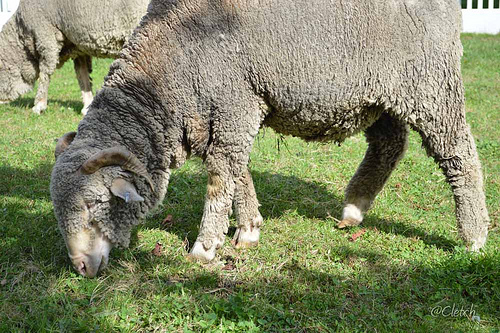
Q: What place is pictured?
A: It is a field.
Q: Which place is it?
A: It is a field.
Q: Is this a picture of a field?
A: Yes, it is showing a field.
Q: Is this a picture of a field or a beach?
A: It is showing a field.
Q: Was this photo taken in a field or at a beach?
A: It was taken at a field.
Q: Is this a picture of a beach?
A: No, the picture is showing a field.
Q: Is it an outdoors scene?
A: Yes, it is outdoors.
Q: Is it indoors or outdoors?
A: It is outdoors.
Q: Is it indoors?
A: No, it is outdoors.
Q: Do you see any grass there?
A: Yes, there is grass.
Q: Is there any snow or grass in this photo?
A: Yes, there is grass.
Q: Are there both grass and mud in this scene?
A: No, there is grass but no mud.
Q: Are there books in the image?
A: No, there are no books.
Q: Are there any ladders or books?
A: No, there are no books or ladders.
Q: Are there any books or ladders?
A: No, there are no books or ladders.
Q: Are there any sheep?
A: Yes, there is a sheep.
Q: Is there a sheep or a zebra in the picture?
A: Yes, there is a sheep.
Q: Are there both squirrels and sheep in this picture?
A: No, there is a sheep but no squirrels.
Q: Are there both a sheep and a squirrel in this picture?
A: No, there is a sheep but no squirrels.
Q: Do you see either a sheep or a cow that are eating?
A: Yes, the sheep is eating.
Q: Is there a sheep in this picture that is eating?
A: Yes, there is a sheep that is eating.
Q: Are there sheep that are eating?
A: Yes, there is a sheep that is eating.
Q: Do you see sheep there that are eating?
A: Yes, there is a sheep that is eating.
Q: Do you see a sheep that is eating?
A: Yes, there is a sheep that is eating.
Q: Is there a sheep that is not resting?
A: Yes, there is a sheep that is eating.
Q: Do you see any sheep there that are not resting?
A: Yes, there is a sheep that is eating .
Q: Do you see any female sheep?
A: Yes, there is a female sheep.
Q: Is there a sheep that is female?
A: Yes, there is a sheep that is female.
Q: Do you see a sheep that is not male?
A: Yes, there is a female sheep.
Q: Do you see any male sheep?
A: Yes, there is a male sheep.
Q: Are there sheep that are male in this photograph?
A: Yes, there is a male sheep.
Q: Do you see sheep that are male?
A: Yes, there is a sheep that is male.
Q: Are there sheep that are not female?
A: Yes, there is a male sheep.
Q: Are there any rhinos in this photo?
A: No, there are no rhinos.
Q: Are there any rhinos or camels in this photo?
A: No, there are no rhinos or camels.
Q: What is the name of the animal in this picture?
A: The animal is a sheep.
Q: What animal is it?
A: The animal is a sheep.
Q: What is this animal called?
A: This is a sheep.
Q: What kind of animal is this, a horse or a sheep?
A: This is a sheep.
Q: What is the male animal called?
A: The animal is a sheep.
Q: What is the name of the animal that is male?
A: The animal is a sheep.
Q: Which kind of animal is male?
A: The animal is a sheep.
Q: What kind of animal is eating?
A: The animal is a sheep.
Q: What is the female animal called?
A: The animal is a sheep.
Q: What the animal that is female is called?
A: The animal is a sheep.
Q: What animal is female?
A: The animal is a sheep.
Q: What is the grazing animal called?
A: The animal is a sheep.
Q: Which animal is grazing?
A: The animal is a sheep.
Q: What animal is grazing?
A: The animal is a sheep.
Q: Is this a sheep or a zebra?
A: This is a sheep.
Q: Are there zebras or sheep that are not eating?
A: No, there is a sheep but he is eating.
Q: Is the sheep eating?
A: Yes, the sheep is eating.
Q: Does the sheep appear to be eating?
A: Yes, the sheep is eating.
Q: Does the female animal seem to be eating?
A: Yes, the sheep is eating.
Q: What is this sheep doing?
A: The sheep is eating.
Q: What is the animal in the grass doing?
A: The sheep is eating.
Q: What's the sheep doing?
A: The sheep is eating.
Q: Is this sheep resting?
A: No, the sheep is eating.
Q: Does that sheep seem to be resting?
A: No, the sheep is eating.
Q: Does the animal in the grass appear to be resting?
A: No, the sheep is eating.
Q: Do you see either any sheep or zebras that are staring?
A: No, there is a sheep but he is eating.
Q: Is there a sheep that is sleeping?
A: No, there is a sheep but he is eating.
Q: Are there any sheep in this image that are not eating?
A: No, there is a sheep but he is eating.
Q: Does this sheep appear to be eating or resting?
A: The sheep is eating.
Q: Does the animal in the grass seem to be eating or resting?
A: The sheep is eating.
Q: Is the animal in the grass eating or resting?
A: The sheep is eating.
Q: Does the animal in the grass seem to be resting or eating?
A: The sheep is eating.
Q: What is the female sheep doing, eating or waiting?
A: The sheep is eating.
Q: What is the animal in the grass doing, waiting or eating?
A: The sheep is eating.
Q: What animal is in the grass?
A: The sheep is in the grass.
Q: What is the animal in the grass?
A: The animal is a sheep.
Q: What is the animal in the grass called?
A: The animal is a sheep.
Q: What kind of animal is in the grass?
A: The animal is a sheep.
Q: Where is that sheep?
A: The sheep is in the grass.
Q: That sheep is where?
A: The sheep is in the grass.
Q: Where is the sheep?
A: The sheep is in the grass.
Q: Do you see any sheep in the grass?
A: Yes, there is a sheep in the grass.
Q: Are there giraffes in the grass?
A: No, there is a sheep in the grass.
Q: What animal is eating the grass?
A: The animal is a sheep.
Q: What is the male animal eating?
A: The sheep is eating grass.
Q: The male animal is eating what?
A: The sheep is eating grass.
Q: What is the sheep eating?
A: The sheep is eating grass.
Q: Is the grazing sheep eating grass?
A: Yes, the sheep is eating grass.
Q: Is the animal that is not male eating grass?
A: Yes, the sheep is eating grass.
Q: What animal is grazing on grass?
A: The sheep is grazing on grass.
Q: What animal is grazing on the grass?
A: The sheep is grazing on grass.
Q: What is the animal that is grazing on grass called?
A: The animal is a sheep.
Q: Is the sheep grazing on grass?
A: Yes, the sheep is grazing on grass.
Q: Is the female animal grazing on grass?
A: Yes, the sheep is grazing on grass.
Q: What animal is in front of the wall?
A: The animal is a sheep.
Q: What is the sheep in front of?
A: The sheep is in front of the wall.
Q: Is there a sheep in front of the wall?
A: Yes, there is a sheep in front of the wall.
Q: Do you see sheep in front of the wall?
A: Yes, there is a sheep in front of the wall.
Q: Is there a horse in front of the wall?
A: No, there is a sheep in front of the wall.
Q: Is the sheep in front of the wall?
A: Yes, the sheep is in front of the wall.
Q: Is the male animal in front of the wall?
A: Yes, the sheep is in front of the wall.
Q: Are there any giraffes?
A: No, there are no giraffes.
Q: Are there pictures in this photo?
A: No, there are no pictures.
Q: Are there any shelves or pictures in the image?
A: No, there are no pictures or shelves.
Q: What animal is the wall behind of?
A: The wall is behind the sheep.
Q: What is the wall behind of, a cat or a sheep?
A: The wall is behind a sheep.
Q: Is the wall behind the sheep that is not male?
A: Yes, the wall is behind the sheep.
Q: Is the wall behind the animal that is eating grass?
A: Yes, the wall is behind the sheep.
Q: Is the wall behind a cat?
A: No, the wall is behind the sheep.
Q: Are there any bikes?
A: No, there are no bikes.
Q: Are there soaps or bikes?
A: No, there are no bikes or soaps.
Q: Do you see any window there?
A: Yes, there are windows.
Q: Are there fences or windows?
A: Yes, there are windows.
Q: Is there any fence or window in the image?
A: Yes, there are windows.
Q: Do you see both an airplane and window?
A: No, there are windows but no airplanes.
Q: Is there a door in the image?
A: No, there are no doors.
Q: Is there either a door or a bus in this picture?
A: No, there are no doors or buses.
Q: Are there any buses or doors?
A: No, there are no doors or buses.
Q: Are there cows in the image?
A: No, there are no cows.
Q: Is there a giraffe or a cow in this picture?
A: No, there are no cows or giraffes.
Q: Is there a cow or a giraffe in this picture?
A: No, there are no cows or giraffes.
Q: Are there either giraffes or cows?
A: No, there are no cows or giraffes.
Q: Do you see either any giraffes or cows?
A: No, there are no cows or giraffes.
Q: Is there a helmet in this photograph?
A: No, there are no helmets.